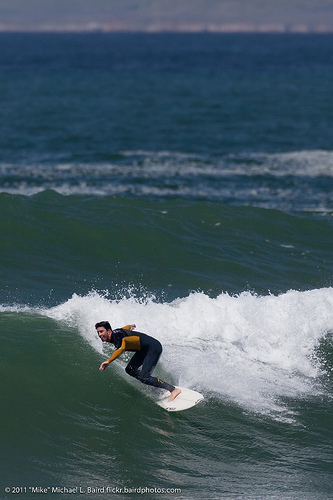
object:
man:
[93, 320, 179, 401]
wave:
[18, 288, 331, 412]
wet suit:
[110, 327, 173, 390]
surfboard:
[147, 378, 203, 413]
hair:
[93, 321, 112, 329]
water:
[1, 32, 332, 499]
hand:
[98, 361, 109, 373]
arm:
[110, 338, 127, 361]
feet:
[167, 388, 180, 402]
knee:
[139, 368, 153, 378]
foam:
[189, 348, 317, 418]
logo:
[154, 374, 165, 385]